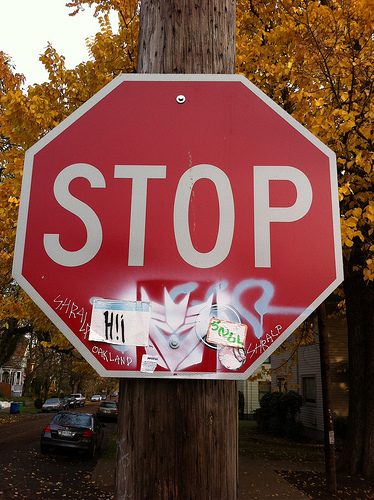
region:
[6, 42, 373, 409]
Stop sign on a wooden post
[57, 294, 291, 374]
graffiti on a stop sign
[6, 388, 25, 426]
a bush along the street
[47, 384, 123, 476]
cars parked on a residential street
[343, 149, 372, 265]
the golden leaves of fall trees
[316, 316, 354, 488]
a wooden pool in the sidewalk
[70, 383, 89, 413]
a white pick up truck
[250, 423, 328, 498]
fallen leaves on the sidewalk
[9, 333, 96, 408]
houses lining the street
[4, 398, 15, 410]
a white picket fence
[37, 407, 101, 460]
car parked on side of street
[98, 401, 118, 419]
car parked on side of street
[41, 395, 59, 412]
car parked on side of street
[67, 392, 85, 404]
car parked on side of street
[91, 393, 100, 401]
car parked on side of street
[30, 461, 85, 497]
loose leaves on street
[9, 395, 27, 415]
blue garbage container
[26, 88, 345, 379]
red traffic sign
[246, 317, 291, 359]
graffiti written on sign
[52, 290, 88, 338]
graffiti written on sign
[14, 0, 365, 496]
Photo taken during the day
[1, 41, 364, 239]
The leaves are yellow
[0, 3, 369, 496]
Photo taken in autumn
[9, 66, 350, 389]
Red stop sign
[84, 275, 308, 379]
Graffiti on the stop sign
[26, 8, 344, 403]
Stop sign affixed to a telephone pole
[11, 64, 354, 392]
The stop sign is an octagon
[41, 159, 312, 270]
The letters are written in white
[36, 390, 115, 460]
Cars parked along the road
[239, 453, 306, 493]
Concrete sidewalk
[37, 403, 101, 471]
car parked side of street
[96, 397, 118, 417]
car parked side of street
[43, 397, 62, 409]
car parked side of street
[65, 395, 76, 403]
car parked side of street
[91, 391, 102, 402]
car parked side of street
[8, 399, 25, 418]
blue trash can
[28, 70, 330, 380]
octagon street sign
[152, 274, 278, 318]
graffiti spray painted on sign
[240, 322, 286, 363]
graffiti spray painted on sign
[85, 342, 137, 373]
graffiti spray painted on sign